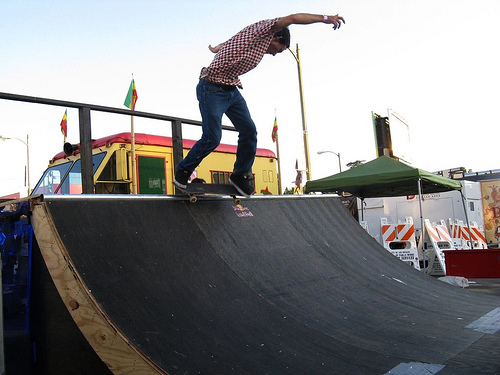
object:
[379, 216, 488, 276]
signs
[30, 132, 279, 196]
food truck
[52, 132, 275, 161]
top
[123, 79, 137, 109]
flag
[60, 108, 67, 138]
flag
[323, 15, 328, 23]
watch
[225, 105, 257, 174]
leg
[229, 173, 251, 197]
foot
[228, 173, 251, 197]
shoe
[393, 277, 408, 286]
white mark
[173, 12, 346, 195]
man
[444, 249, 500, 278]
fence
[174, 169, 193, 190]
feet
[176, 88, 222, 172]
leg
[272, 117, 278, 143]
flag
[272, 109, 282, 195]
pole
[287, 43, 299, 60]
light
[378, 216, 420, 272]
barrier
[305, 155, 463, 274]
green tent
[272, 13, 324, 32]
arm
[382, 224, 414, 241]
orange/white stripes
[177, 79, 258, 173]
blue jeans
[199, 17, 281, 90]
shirt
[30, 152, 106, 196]
windows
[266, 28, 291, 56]
head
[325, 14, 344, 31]
hand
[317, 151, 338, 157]
light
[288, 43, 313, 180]
light pole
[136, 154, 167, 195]
window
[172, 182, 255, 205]
skateboard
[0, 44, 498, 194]
background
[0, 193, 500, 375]
ramp